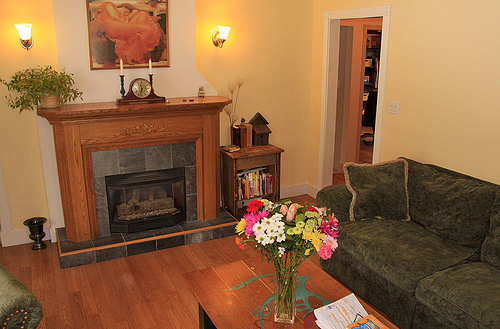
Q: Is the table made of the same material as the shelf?
A: Yes, both the table and the shelf are made of wood.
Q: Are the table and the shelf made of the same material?
A: Yes, both the table and the shelf are made of wood.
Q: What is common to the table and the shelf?
A: The material, both the table and the shelf are wooden.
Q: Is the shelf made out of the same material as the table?
A: Yes, both the shelf and the table are made of wood.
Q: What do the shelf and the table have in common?
A: The material, both the shelf and the table are wooden.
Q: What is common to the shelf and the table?
A: The material, both the shelf and the table are wooden.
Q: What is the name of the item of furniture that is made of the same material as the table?
A: The piece of furniture is a shelf.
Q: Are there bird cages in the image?
A: No, there are no bird cages.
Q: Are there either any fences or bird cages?
A: No, there are no bird cages or fences.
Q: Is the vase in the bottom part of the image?
A: Yes, the vase is in the bottom of the image.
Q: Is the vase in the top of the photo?
A: No, the vase is in the bottom of the image.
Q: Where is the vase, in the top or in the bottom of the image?
A: The vase is in the bottom of the image.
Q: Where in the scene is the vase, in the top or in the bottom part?
A: The vase is in the bottom of the image.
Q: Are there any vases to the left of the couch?
A: Yes, there is a vase to the left of the couch.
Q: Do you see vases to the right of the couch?
A: No, the vase is to the left of the couch.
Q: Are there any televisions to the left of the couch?
A: No, there is a vase to the left of the couch.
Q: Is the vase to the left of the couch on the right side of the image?
A: Yes, the vase is to the left of the couch.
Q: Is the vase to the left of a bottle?
A: No, the vase is to the left of the couch.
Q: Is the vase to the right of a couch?
A: No, the vase is to the left of a couch.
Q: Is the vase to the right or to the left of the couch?
A: The vase is to the left of the couch.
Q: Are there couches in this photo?
A: Yes, there is a couch.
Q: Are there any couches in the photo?
A: Yes, there is a couch.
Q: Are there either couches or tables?
A: Yes, there is a couch.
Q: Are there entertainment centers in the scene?
A: No, there are no entertainment centers.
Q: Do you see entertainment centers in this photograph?
A: No, there are no entertainment centers.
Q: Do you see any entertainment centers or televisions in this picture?
A: No, there are no entertainment centers or televisions.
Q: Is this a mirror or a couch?
A: This is a couch.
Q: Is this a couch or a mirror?
A: This is a couch.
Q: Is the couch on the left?
A: No, the couch is on the right of the image.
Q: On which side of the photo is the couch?
A: The couch is on the right of the image.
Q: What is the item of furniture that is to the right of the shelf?
A: The piece of furniture is a couch.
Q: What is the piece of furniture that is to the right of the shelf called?
A: The piece of furniture is a couch.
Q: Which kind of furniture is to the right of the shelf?
A: The piece of furniture is a couch.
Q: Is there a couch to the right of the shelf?
A: Yes, there is a couch to the right of the shelf.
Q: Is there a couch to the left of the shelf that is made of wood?
A: No, the couch is to the right of the shelf.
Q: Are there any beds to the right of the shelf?
A: No, there is a couch to the right of the shelf.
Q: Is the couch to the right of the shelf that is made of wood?
A: Yes, the couch is to the right of the shelf.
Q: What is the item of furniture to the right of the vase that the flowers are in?
A: The piece of furniture is a couch.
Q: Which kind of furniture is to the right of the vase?
A: The piece of furniture is a couch.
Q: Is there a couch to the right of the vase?
A: Yes, there is a couch to the right of the vase.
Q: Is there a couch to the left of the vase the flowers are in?
A: No, the couch is to the right of the vase.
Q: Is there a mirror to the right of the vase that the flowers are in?
A: No, there is a couch to the right of the vase.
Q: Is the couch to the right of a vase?
A: Yes, the couch is to the right of a vase.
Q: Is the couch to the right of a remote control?
A: No, the couch is to the right of a vase.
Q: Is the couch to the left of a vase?
A: No, the couch is to the right of a vase.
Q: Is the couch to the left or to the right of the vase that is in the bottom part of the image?
A: The couch is to the right of the vase.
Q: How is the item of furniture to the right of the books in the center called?
A: The piece of furniture is a couch.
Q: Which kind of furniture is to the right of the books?
A: The piece of furniture is a couch.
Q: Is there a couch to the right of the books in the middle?
A: Yes, there is a couch to the right of the books.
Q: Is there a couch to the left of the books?
A: No, the couch is to the right of the books.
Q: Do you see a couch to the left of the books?
A: No, the couch is to the right of the books.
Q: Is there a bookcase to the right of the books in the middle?
A: No, there is a couch to the right of the books.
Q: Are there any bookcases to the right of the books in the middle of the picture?
A: No, there is a couch to the right of the books.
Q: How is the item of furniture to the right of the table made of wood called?
A: The piece of furniture is a couch.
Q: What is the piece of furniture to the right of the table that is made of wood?
A: The piece of furniture is a couch.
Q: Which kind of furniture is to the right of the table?
A: The piece of furniture is a couch.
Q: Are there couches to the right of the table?
A: Yes, there is a couch to the right of the table.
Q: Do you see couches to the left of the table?
A: No, the couch is to the right of the table.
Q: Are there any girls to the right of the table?
A: No, there is a couch to the right of the table.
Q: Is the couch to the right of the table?
A: Yes, the couch is to the right of the table.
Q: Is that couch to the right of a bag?
A: No, the couch is to the right of the table.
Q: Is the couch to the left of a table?
A: No, the couch is to the right of a table.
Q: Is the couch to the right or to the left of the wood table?
A: The couch is to the right of the table.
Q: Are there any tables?
A: Yes, there is a table.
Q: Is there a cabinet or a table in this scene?
A: Yes, there is a table.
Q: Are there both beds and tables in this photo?
A: No, there is a table but no beds.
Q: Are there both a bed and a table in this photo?
A: No, there is a table but no beds.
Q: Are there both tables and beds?
A: No, there is a table but no beds.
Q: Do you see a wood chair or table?
A: Yes, there is a wood table.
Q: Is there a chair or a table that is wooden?
A: Yes, the table is wooden.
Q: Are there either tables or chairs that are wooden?
A: Yes, the table is wooden.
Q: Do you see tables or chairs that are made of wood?
A: Yes, the table is made of wood.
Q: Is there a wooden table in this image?
A: Yes, there is a wood table.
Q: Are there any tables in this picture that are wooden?
A: Yes, there is a table that is wooden.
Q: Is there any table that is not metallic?
A: Yes, there is a wooden table.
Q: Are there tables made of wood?
A: Yes, there is a table that is made of wood.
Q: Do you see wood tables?
A: Yes, there is a table that is made of wood.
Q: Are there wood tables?
A: Yes, there is a table that is made of wood.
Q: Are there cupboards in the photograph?
A: No, there are no cupboards.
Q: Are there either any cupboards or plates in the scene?
A: No, there are no cupboards or plates.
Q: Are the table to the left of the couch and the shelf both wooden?
A: Yes, both the table and the shelf are wooden.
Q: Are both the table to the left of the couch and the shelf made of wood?
A: Yes, both the table and the shelf are made of wood.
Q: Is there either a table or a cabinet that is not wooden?
A: No, there is a table but it is wooden.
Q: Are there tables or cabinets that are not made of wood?
A: No, there is a table but it is made of wood.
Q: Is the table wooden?
A: Yes, the table is wooden.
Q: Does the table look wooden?
A: Yes, the table is wooden.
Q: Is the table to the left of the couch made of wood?
A: Yes, the table is made of wood.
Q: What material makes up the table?
A: The table is made of wood.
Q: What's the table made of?
A: The table is made of wood.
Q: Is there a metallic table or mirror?
A: No, there is a table but it is wooden.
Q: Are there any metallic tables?
A: No, there is a table but it is wooden.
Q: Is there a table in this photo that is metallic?
A: No, there is a table but it is wooden.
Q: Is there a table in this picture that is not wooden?
A: No, there is a table but it is wooden.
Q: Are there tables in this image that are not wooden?
A: No, there is a table but it is wooden.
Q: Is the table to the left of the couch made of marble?
A: No, the table is made of wood.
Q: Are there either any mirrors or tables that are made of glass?
A: No, there is a table but it is made of wood.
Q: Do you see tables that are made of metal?
A: No, there is a table but it is made of wood.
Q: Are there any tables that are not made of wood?
A: No, there is a table but it is made of wood.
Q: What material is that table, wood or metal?
A: The table is made of wood.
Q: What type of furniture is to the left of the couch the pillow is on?
A: The piece of furniture is a table.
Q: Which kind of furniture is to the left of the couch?
A: The piece of furniture is a table.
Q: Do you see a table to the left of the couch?
A: Yes, there is a table to the left of the couch.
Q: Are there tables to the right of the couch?
A: No, the table is to the left of the couch.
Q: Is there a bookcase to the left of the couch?
A: No, there is a table to the left of the couch.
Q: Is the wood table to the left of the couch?
A: Yes, the table is to the left of the couch.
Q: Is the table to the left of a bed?
A: No, the table is to the left of the couch.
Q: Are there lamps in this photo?
A: Yes, there is a lamp.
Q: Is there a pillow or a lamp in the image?
A: Yes, there is a lamp.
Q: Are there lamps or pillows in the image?
A: Yes, there is a lamp.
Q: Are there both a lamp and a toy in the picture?
A: No, there is a lamp but no toys.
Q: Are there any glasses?
A: No, there are no glasses.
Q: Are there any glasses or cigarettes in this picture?
A: No, there are no glasses or cigarettes.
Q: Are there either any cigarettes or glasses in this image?
A: No, there are no glasses or cigarettes.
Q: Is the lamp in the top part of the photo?
A: Yes, the lamp is in the top of the image.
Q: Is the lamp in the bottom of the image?
A: No, the lamp is in the top of the image.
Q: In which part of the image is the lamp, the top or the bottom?
A: The lamp is in the top of the image.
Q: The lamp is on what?
A: The lamp is on the wall.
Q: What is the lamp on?
A: The lamp is on the wall.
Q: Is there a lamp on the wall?
A: Yes, there is a lamp on the wall.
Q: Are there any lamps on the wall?
A: Yes, there is a lamp on the wall.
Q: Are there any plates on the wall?
A: No, there is a lamp on the wall.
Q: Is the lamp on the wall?
A: Yes, the lamp is on the wall.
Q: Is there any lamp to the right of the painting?
A: Yes, there is a lamp to the right of the painting.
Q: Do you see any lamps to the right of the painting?
A: Yes, there is a lamp to the right of the painting.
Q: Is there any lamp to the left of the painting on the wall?
A: No, the lamp is to the right of the painting.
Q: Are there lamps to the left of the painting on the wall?
A: No, the lamp is to the right of the painting.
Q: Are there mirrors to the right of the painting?
A: No, there is a lamp to the right of the painting.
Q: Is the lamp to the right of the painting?
A: Yes, the lamp is to the right of the painting.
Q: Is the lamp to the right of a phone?
A: No, the lamp is to the right of the painting.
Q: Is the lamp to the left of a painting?
A: No, the lamp is to the right of a painting.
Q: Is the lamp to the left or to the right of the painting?
A: The lamp is to the right of the painting.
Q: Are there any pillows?
A: Yes, there is a pillow.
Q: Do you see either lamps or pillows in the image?
A: Yes, there is a pillow.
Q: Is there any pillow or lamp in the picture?
A: Yes, there is a pillow.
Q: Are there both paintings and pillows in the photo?
A: Yes, there are both a pillow and a painting.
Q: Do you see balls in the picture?
A: No, there are no balls.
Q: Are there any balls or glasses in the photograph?
A: No, there are no balls or glasses.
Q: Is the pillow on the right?
A: Yes, the pillow is on the right of the image.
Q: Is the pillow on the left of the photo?
A: No, the pillow is on the right of the image.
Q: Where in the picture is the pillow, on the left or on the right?
A: The pillow is on the right of the image.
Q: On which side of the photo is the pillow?
A: The pillow is on the right of the image.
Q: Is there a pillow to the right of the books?
A: Yes, there is a pillow to the right of the books.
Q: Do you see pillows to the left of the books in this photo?
A: No, the pillow is to the right of the books.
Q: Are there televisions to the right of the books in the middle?
A: No, there is a pillow to the right of the books.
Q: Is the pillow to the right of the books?
A: Yes, the pillow is to the right of the books.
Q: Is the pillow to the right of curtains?
A: No, the pillow is to the right of the books.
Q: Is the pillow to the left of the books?
A: No, the pillow is to the right of the books.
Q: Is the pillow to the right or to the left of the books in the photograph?
A: The pillow is to the right of the books.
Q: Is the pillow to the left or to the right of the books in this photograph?
A: The pillow is to the right of the books.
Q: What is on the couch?
A: The pillow is on the couch.